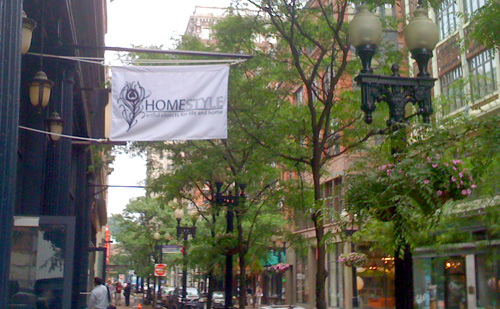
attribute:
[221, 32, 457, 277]
trees — growing, tall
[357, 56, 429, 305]
lamppost — black, iron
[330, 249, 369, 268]
basket — hanging, lush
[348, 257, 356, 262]
flowers — pink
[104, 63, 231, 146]
banner — white, hanging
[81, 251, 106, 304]
door — open, reflecting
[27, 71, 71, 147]
fixtures — lights, hanging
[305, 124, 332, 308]
trunk — thin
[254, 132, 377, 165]
branches — angled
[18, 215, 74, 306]
door — glass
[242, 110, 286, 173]
leaves — green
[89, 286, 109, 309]
shirt — white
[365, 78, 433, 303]
pole — black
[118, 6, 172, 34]
sky — white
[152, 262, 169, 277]
sign — red